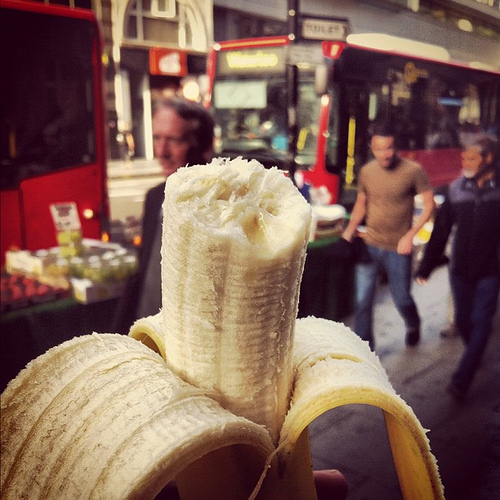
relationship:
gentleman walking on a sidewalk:
[335, 121, 437, 353] [367, 320, 459, 417]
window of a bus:
[428, 78, 496, 146] [189, 29, 483, 206]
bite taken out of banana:
[158, 152, 314, 261] [9, 145, 466, 497]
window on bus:
[216, 52, 300, 154] [189, 29, 483, 206]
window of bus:
[366, 91, 380, 126] [189, 29, 483, 206]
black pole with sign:
[283, 0, 299, 176] [296, 17, 349, 41]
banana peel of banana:
[0, 313, 447, 500] [9, 145, 466, 497]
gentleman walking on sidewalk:
[411, 137, 498, 403] [381, 326, 457, 417]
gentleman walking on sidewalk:
[335, 121, 437, 353] [381, 326, 457, 417]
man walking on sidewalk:
[108, 95, 217, 346] [381, 326, 457, 417]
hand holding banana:
[271, 466, 359, 498] [9, 145, 466, 497]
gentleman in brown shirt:
[335, 121, 437, 353] [354, 155, 431, 246]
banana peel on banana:
[0, 313, 447, 500] [138, 157, 323, 423]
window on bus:
[342, 83, 384, 139] [189, 29, 483, 206]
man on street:
[108, 90, 228, 346] [2, 211, 498, 496]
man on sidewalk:
[108, 95, 217, 346] [7, 232, 499, 489]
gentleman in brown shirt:
[335, 121, 437, 353] [356, 158, 431, 250]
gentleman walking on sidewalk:
[335, 121, 437, 353] [289, 266, 464, 497]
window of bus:
[211, 45, 326, 161] [189, 29, 483, 206]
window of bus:
[388, 84, 419, 122] [189, 29, 483, 206]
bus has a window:
[189, 29, 483, 206] [418, 73, 453, 143]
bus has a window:
[189, 29, 483, 206] [439, 76, 483, 138]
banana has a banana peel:
[162, 165, 312, 430] [0, 313, 447, 500]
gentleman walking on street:
[341, 121, 437, 352] [303, 239, 499, 499]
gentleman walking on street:
[411, 141, 499, 404] [303, 239, 499, 499]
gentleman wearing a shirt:
[411, 137, 498, 403] [415, 173, 498, 279]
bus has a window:
[189, 29, 483, 206] [216, 75, 332, 156]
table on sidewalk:
[4, 200, 364, 380] [286, 227, 489, 499]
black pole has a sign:
[283, 5, 299, 177] [296, 17, 349, 41]